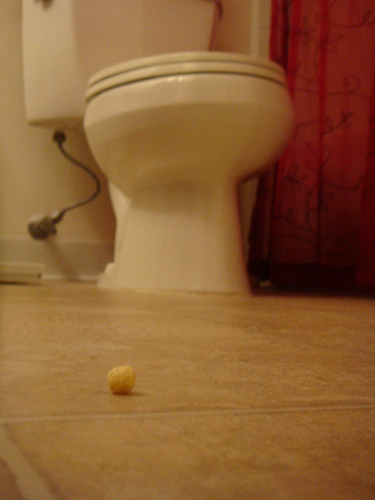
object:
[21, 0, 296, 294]
toilet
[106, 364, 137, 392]
corn puff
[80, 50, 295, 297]
toilet seat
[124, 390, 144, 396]
shadow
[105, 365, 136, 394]
food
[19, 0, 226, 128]
toilet tank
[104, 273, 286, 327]
caulking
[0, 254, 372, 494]
area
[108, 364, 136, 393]
cereal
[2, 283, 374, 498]
floor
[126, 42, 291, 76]
toilet lead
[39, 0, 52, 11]
handle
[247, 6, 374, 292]
curtain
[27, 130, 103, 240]
pipe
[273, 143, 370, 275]
flowers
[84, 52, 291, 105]
seat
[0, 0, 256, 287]
wall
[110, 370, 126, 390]
piece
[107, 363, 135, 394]
ball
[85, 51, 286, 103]
lid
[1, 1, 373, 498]
bathroom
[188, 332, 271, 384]
part